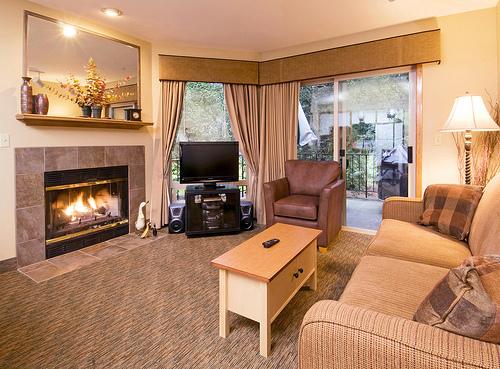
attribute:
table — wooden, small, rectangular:
[211, 220, 322, 357]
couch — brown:
[296, 169, 499, 367]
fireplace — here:
[41, 160, 130, 259]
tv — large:
[178, 141, 241, 183]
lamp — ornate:
[438, 91, 499, 187]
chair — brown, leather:
[263, 159, 347, 252]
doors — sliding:
[292, 66, 420, 234]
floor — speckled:
[1, 221, 377, 368]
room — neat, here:
[1, 1, 499, 368]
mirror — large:
[17, 10, 149, 124]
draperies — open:
[151, 80, 301, 228]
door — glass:
[300, 66, 413, 236]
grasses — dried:
[452, 91, 499, 186]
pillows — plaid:
[412, 181, 499, 346]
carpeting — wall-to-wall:
[1, 223, 377, 366]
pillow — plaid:
[419, 183, 485, 242]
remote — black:
[261, 237, 281, 249]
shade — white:
[439, 95, 499, 136]